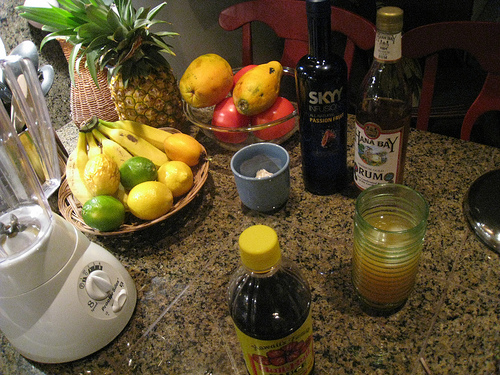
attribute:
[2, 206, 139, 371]
blender — white, empty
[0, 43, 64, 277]
pitcher — empty, clear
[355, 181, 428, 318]
glass — green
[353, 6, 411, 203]
bottle of rum — here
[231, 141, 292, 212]
coffee mug — blue, small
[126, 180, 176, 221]
lemon — yellow, bright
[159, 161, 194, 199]
lemon — bright, yellow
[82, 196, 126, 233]
lime — green, bright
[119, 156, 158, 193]
lime — bright, green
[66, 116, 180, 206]
bananas — yellow, bright, bunched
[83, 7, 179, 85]
leaves — green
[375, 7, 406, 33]
cap — plastic, yellow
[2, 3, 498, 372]
countertop — granite